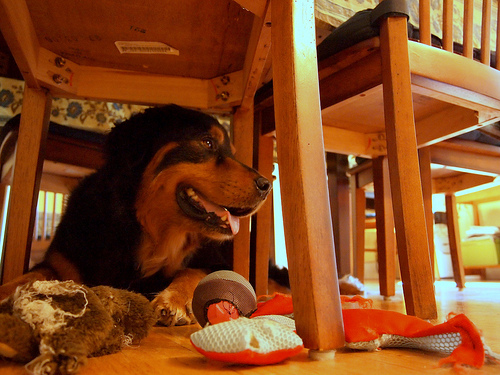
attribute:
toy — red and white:
[185, 307, 310, 374]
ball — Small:
[191, 267, 262, 321]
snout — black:
[258, 177, 270, 194]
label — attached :
[115, 40, 179, 57]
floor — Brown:
[135, 324, 202, 374]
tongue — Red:
[199, 198, 244, 236]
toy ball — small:
[190, 265, 268, 324]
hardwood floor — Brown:
[128, 342, 198, 371]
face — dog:
[129, 112, 281, 247]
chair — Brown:
[252, 0, 499, 321]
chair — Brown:
[347, 127, 499, 292]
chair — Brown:
[0, 0, 349, 362]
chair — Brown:
[0, 110, 115, 241]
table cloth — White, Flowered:
[4, 80, 235, 150]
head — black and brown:
[98, 101, 269, 243]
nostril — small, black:
[258, 181, 271, 197]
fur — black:
[100, 103, 212, 215]